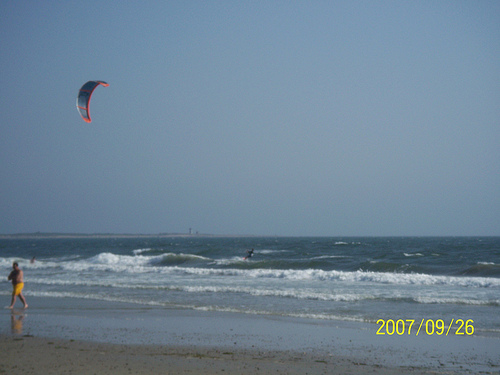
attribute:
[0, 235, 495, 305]
water — blue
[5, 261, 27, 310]
man — shirtless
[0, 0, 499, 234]
sky — blue, cloudless, hazy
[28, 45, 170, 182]
kite — blue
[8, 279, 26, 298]
shorts — yellow